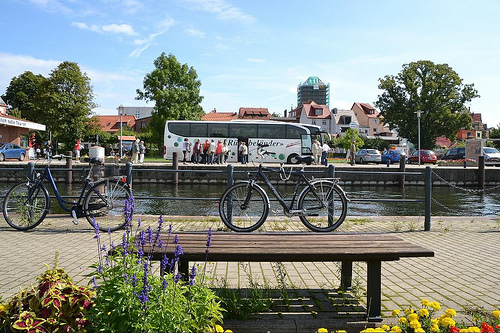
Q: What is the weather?
A: Sunny.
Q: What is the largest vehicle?
A: Bus.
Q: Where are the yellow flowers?
A: Bottom right.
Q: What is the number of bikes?
A: 2.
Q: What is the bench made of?
A: Wood.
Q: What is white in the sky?
A: Clouds.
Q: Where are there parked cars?
A: Other side of canal.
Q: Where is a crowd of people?
A: Side of bus.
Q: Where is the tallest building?
A: Behind houses.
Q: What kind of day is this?
A: Bright and sunny.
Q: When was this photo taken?
A: During the daytime.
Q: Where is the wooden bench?
A: In front of the bicycles.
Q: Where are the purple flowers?
A: In front of the wooden bench.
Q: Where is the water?
A: Between the bicycles and the bus.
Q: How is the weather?
A: Sunny and clear.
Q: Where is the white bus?
A: In the background near the water.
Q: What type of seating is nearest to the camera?
A: A bench.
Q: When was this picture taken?
A: Daytime.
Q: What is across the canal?
A: A tour bus.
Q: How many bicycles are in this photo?
A: Two.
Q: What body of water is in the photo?
A: A canal.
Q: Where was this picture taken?
A: Outside near a canal.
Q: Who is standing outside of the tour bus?
A: People waiting to board.